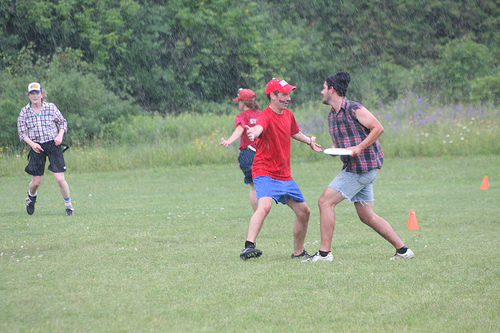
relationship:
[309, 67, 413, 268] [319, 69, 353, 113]
man has head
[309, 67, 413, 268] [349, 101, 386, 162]
man has arm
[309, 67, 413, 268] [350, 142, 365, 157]
man has hand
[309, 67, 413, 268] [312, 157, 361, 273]
man has leg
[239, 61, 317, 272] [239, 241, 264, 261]
man wearing shoe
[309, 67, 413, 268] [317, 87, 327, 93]
man has nose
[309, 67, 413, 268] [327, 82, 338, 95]
man has ear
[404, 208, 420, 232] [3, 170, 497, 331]
cones on grass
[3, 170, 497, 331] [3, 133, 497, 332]
grass on ground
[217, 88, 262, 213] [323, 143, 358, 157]
woman playing frisbee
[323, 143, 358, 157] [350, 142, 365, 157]
frisbee in hand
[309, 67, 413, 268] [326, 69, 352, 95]
man wearing hat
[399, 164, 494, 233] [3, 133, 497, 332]
cones on ground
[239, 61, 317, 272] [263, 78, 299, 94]
man wearing hat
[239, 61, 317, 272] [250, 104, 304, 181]
man wearing shirt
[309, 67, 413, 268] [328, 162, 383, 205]
man wearing shorts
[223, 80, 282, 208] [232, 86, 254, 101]
woman wearing hat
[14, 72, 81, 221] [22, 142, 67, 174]
man wearing shorts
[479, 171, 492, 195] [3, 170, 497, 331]
cone on grass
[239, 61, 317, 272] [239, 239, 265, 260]
man has foot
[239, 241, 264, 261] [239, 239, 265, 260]
shoe on foot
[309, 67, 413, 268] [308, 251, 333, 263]
man has foot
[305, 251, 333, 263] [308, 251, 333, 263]
shoe on foot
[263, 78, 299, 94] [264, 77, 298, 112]
hat on head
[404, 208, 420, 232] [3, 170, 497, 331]
cones in grass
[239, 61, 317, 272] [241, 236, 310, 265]
man wearing shoes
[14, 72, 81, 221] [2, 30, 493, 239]
man in background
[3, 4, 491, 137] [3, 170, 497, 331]
trees behind grass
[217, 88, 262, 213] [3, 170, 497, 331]
woman in grass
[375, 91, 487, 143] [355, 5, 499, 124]
flowers near tree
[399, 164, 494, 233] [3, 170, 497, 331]
cones on grass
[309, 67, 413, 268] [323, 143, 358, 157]
man holding frisbee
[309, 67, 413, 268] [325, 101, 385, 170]
man wearing shirt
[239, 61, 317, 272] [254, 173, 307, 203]
man wearing shorts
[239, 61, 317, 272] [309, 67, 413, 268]
man blocking man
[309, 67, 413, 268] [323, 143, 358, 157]
man with frisbee